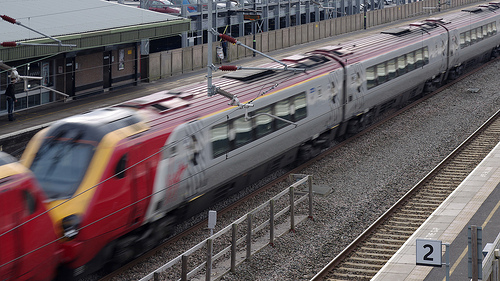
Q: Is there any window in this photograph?
A: Yes, there is a window.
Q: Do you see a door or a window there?
A: Yes, there is a window.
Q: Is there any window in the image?
A: Yes, there are windows.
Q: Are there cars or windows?
A: Yes, there are windows.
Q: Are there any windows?
A: Yes, there are windows.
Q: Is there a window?
A: Yes, there are windows.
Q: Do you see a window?
A: Yes, there are windows.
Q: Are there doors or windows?
A: Yes, there are windows.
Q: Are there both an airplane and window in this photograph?
A: No, there are windows but no airplanes.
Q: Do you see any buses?
A: No, there are no buses.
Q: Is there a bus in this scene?
A: No, there are no buses.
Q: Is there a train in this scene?
A: Yes, there is a train.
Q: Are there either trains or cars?
A: Yes, there is a train.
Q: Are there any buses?
A: No, there are no buses.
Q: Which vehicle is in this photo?
A: The vehicle is a train.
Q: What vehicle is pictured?
A: The vehicle is a train.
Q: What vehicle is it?
A: The vehicle is a train.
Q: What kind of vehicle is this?
A: That is a train.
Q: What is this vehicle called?
A: That is a train.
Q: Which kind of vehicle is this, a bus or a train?
A: That is a train.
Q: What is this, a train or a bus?
A: This is a train.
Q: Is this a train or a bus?
A: This is a train.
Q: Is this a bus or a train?
A: This is a train.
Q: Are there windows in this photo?
A: Yes, there is a window.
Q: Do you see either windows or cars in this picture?
A: Yes, there is a window.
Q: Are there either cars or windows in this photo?
A: Yes, there is a window.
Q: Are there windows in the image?
A: Yes, there is a window.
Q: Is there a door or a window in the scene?
A: Yes, there is a window.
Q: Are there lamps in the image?
A: No, there are no lamps.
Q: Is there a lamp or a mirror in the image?
A: No, there are no lamps or mirrors.